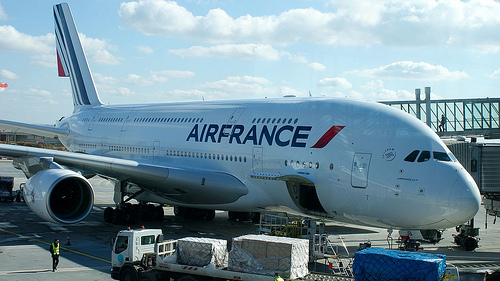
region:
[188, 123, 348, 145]
Red and blue logo on side of airplane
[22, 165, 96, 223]
Airplane engine under wing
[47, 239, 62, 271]
Man in orange and yellow vest near plane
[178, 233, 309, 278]
Cargo on back of flatbed truck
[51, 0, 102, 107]
Tail on back of plane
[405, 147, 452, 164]
Cockpit windows on front of plane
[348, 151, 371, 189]
Closed door on side of plane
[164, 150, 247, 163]
Group of windows on side of plane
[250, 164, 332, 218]
Open cargo door on plane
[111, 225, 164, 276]
White cab on flatbed truck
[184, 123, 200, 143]
The letter is blue.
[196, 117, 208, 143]
The letter is blue.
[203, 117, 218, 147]
The letter is blue.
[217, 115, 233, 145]
The letter is blue.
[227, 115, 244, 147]
The letter is blue.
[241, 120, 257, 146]
The letter is blue.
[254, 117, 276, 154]
The letter is blue.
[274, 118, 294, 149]
The letter is blue.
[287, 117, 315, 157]
The letter is blue.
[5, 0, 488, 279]
The plane is sitting on the ground.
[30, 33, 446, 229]
airplane at airport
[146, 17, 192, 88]
white clouds in blue sky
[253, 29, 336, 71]
white clouds in blue sky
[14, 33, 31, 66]
white clouds in blue sky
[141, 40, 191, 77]
white clouds in blue sky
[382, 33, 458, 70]
white clouds in blue sky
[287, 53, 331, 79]
white clouds in blue sky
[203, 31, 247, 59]
white clouds in blue sky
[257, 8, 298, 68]
white clouds in blue sky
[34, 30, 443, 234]
white airplane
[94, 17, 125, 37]
white clouds in blue sky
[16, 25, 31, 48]
white clouds in blue sky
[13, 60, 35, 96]
white clouds in blue sky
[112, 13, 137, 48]
white clouds in blue sky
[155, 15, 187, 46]
white clouds in blue sky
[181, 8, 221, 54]
white clouds in blue sky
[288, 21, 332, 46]
white clouds in blue sky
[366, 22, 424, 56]
white clouds in blue sky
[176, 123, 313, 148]
blue writing on an airplane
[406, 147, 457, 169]
windows in a cock pit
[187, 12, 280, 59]
fluffy white clouds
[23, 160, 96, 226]
engine underneath a wing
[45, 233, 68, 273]
person in a yellow vest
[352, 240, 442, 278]
blue covered luggage carrier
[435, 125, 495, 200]
walkway to board an airplane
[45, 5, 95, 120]
stripes on an airplane's tail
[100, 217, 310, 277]
truck hauling an airplane's cargo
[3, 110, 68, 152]
hills in the distance